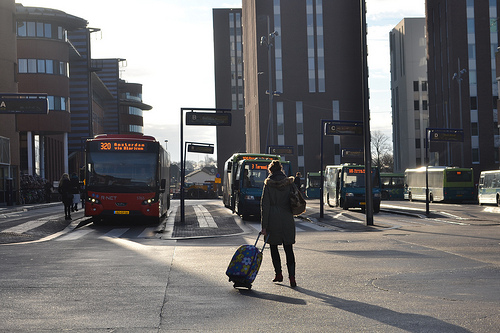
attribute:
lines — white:
[24, 208, 98, 252]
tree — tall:
[371, 127, 390, 166]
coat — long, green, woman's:
[263, 175, 305, 244]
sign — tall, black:
[428, 129, 470, 144]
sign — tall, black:
[320, 121, 367, 136]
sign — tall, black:
[181, 105, 233, 128]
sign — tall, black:
[189, 139, 217, 154]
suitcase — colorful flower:
[226, 229, 271, 293]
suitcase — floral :
[221, 239, 262, 294]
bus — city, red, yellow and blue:
[82, 131, 169, 228]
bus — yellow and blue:
[323, 163, 380, 210]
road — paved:
[4, 198, 497, 332]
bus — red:
[325, 159, 379, 211]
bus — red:
[401, 160, 477, 204]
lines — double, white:
[185, 200, 226, 236]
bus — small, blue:
[60, 98, 190, 230]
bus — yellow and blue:
[402, 167, 479, 206]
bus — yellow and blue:
[228, 158, 289, 220]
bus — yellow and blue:
[479, 169, 499, 205]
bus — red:
[70, 121, 181, 246]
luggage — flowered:
[193, 225, 299, 302]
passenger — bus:
[258, 159, 303, 291]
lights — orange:
[101, 141, 150, 153]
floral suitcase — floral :
[221, 223, 274, 292]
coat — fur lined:
[254, 163, 305, 253]